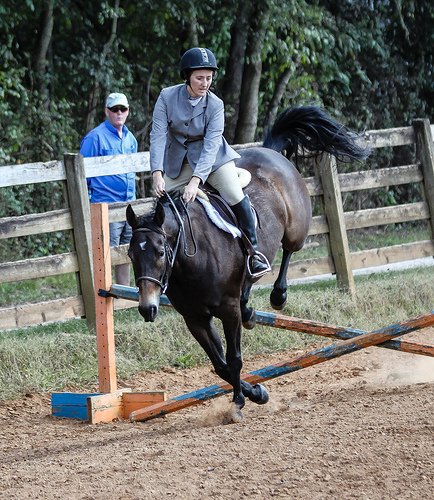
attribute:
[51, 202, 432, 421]
jump — wooden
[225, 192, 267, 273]
boot — black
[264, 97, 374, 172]
tail — black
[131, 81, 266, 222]
woman — young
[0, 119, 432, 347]
fence — wooden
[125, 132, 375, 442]
horse — black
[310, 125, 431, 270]
fence — wooden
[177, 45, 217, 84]
hat — black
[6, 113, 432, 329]
fence — wooden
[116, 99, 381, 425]
horse — black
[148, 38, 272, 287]
rider — young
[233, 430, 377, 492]
path — dirt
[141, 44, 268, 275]
woman — young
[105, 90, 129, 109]
hat — white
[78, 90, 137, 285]
man — older, old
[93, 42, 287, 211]
man — old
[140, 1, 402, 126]
trees — green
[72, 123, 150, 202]
shirt — blue, long sleeved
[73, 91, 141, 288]
man — old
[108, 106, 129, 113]
sunglasses — black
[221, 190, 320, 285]
boot — black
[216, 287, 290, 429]
hooves — black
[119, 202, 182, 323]
head. — large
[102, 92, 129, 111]
cap — white 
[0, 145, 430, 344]
fence — wooden, long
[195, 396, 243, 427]
dirt — brown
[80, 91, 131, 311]
man — old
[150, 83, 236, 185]
jacket — light gray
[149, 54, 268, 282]
woman — young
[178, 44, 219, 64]
safety helmet — black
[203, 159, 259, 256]
leg — long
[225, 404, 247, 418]
hoof — black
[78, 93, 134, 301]
man — old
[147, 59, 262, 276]
rider — young